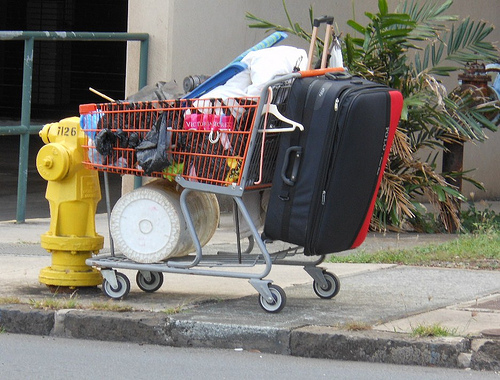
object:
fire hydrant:
[32, 115, 105, 292]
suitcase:
[262, 14, 405, 256]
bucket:
[107, 179, 222, 264]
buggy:
[79, 75, 399, 314]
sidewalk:
[0, 242, 500, 369]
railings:
[0, 29, 151, 224]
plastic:
[133, 114, 176, 171]